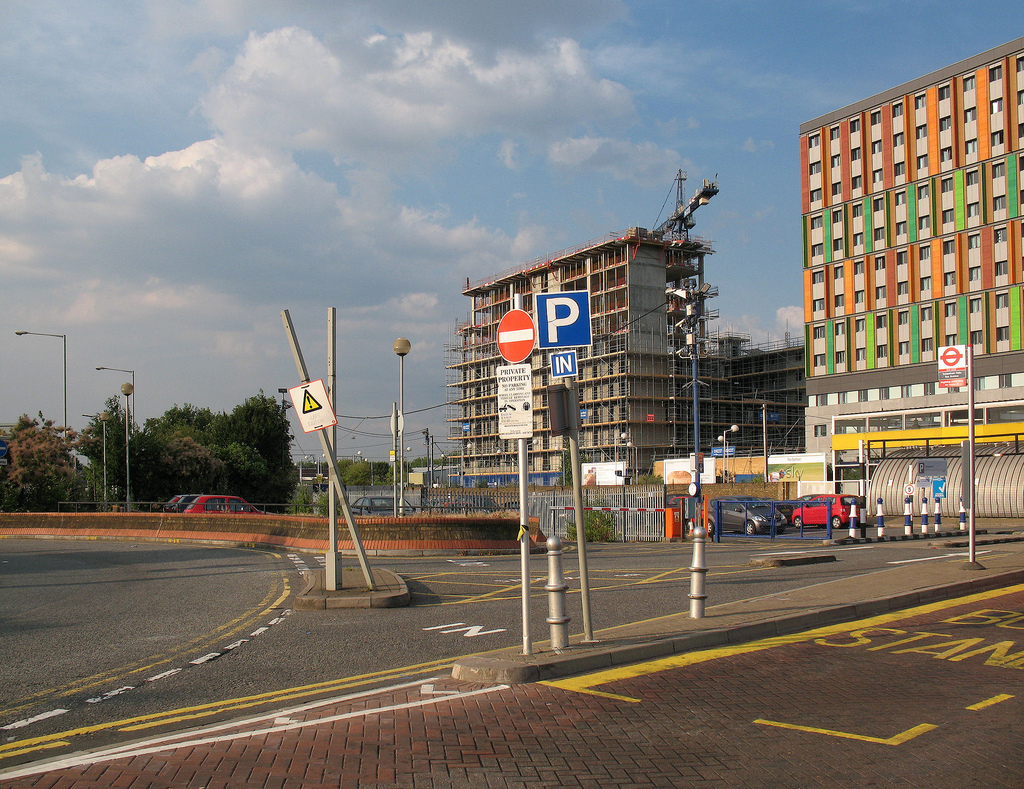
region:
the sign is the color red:
[498, 312, 540, 361]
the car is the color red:
[183, 496, 256, 517]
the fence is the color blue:
[710, 496, 835, 539]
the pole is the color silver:
[540, 538, 575, 646]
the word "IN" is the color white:
[426, 616, 503, 637]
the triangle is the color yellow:
[303, 389, 324, 418]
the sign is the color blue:
[550, 354, 577, 378]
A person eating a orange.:
[318, 470, 497, 648]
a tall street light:
[16, 322, 73, 439]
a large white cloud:
[187, 18, 631, 142]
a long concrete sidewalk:
[453, 546, 1020, 684]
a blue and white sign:
[535, 288, 594, 343]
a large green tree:
[222, 386, 298, 491]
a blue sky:
[792, 6, 1015, 87]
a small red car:
[791, 489, 861, 524]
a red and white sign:
[490, 301, 544, 362]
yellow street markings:
[544, 587, 1022, 780]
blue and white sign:
[527, 277, 608, 358]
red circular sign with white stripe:
[480, 302, 547, 360]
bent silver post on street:
[265, 301, 395, 599]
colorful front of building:
[760, 89, 1001, 358]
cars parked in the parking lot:
[153, 474, 340, 526]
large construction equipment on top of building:
[586, 140, 748, 277]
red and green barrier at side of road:
[66, 448, 518, 569]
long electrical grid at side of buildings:
[251, 345, 508, 462]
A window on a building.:
[812, 326, 828, 340]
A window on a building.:
[878, 343, 888, 353]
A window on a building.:
[897, 307, 913, 330]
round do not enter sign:
[487, 289, 535, 366]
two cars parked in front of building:
[718, 485, 868, 537]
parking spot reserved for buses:
[535, 563, 1016, 759]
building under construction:
[459, 232, 802, 479]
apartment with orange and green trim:
[804, 79, 1020, 447]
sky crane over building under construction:
[664, 164, 725, 248]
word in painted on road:
[422, 601, 496, 643]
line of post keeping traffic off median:
[829, 497, 978, 543]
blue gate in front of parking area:
[706, 499, 833, 551]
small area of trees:
[4, 398, 302, 520]